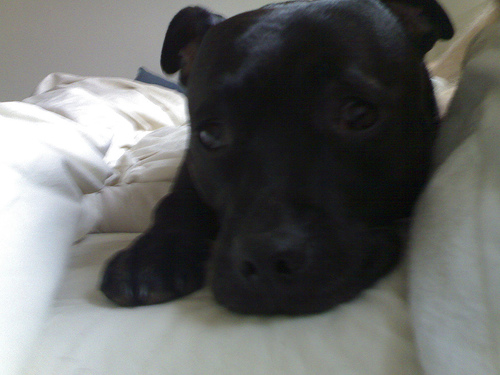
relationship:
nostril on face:
[241, 259, 256, 282] [159, 0, 454, 317]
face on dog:
[159, 0, 454, 317] [96, 2, 456, 316]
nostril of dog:
[241, 259, 256, 282] [96, 2, 456, 316]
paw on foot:
[101, 250, 206, 305] [98, 157, 219, 309]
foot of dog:
[98, 157, 219, 309] [96, 2, 456, 316]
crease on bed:
[73, 117, 190, 243] [1, 1, 499, 374]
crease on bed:
[144, 124, 191, 142] [1, 1, 499, 374]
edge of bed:
[0, 71, 187, 124] [1, 1, 499, 374]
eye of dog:
[197, 120, 238, 150] [96, 2, 456, 316]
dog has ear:
[96, 2, 456, 316] [160, 5, 228, 88]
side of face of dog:
[366, 61, 440, 289] [96, 2, 456, 316]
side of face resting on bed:
[366, 61, 440, 289] [1, 1, 499, 374]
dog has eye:
[96, 2, 456, 316] [197, 120, 238, 150]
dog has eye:
[96, 2, 456, 316] [339, 99, 378, 131]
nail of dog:
[137, 283, 151, 301] [96, 2, 456, 316]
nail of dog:
[121, 286, 134, 300] [96, 2, 456, 316]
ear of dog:
[160, 5, 228, 88] [96, 2, 456, 316]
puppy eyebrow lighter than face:
[328, 63, 386, 94] [159, 0, 454, 317]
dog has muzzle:
[96, 2, 456, 316] [209, 181, 405, 316]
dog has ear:
[96, 2, 456, 316] [379, 0, 456, 57]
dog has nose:
[96, 2, 456, 316] [230, 227, 314, 291]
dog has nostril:
[96, 2, 456, 316] [241, 259, 256, 282]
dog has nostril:
[96, 2, 456, 316] [275, 258, 291, 274]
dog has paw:
[96, 2, 456, 316] [101, 250, 206, 305]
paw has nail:
[101, 250, 206, 305] [137, 283, 151, 301]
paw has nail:
[101, 250, 206, 305] [121, 286, 134, 300]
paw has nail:
[101, 250, 206, 305] [173, 273, 186, 292]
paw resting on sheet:
[101, 250, 206, 305] [17, 232, 424, 374]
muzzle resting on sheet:
[209, 181, 405, 316] [17, 232, 424, 374]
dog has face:
[96, 2, 456, 316] [159, 0, 454, 317]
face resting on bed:
[159, 0, 454, 317] [1, 1, 499, 374]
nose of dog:
[230, 227, 314, 291] [96, 2, 456, 316]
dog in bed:
[96, 2, 456, 316] [1, 1, 499, 374]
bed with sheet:
[1, 1, 499, 374] [17, 232, 424, 374]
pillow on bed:
[133, 67, 184, 94] [1, 1, 499, 374]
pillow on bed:
[404, 1, 500, 375] [1, 1, 499, 374]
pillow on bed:
[425, 1, 495, 84] [1, 1, 499, 374]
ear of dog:
[379, 0, 456, 57] [96, 2, 456, 316]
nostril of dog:
[275, 258, 291, 274] [96, 2, 456, 316]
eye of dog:
[339, 99, 378, 131] [96, 2, 456, 316]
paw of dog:
[101, 250, 206, 305] [96, 2, 456, 316]